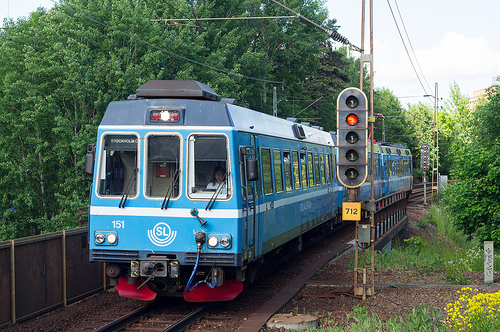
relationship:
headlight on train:
[208, 235, 217, 246] [83, 81, 413, 300]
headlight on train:
[208, 235, 229, 247] [63, 75, 448, 304]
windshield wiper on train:
[205, 170, 230, 209] [83, 81, 413, 300]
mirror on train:
[84, 153, 96, 175] [83, 81, 413, 300]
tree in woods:
[5, 25, 75, 239] [0, 11, 330, 83]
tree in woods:
[447, 77, 498, 240] [0, 2, 498, 330]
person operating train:
[197, 168, 225, 192] [83, 81, 413, 300]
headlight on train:
[155, 106, 177, 123] [83, 81, 413, 300]